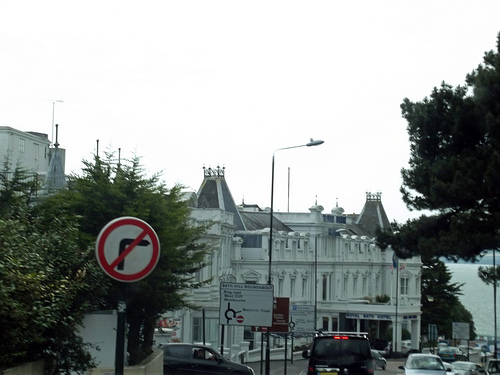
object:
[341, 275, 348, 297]
window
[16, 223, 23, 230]
leaf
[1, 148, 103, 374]
plant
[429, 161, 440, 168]
leaf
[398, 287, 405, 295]
window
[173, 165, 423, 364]
building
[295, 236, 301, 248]
window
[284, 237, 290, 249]
window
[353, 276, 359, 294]
window